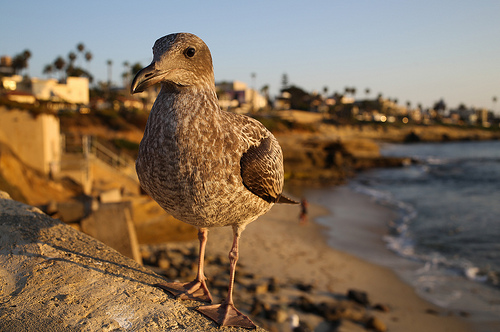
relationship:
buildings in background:
[270, 85, 321, 115] [223, 22, 495, 120]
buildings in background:
[449, 105, 488, 125] [223, 22, 495, 120]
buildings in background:
[353, 100, 415, 120] [223, 22, 495, 120]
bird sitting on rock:
[128, 30, 302, 329] [2, 198, 208, 330]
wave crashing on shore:
[391, 225, 470, 292] [360, 217, 484, 328]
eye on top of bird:
[183, 46, 200, 58] [128, 30, 302, 329]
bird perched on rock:
[128, 30, 302, 329] [1, 197, 270, 329]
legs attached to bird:
[153, 226, 262, 330] [128, 30, 302, 329]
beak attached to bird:
[126, 63, 168, 94] [128, 30, 302, 329]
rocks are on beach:
[259, 276, 309, 316] [242, 251, 471, 331]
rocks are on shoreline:
[328, 144, 405, 176] [331, 164, 445, 295]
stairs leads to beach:
[81, 133, 132, 178] [313, 190, 435, 330]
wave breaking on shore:
[391, 225, 470, 292] [313, 173, 455, 311]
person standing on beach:
[299, 197, 311, 219] [158, 170, 433, 327]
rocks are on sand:
[259, 276, 379, 326] [89, 161, 430, 330]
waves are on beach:
[353, 172, 497, 292] [293, 171, 463, 303]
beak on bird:
[126, 63, 168, 94] [107, 24, 332, 268]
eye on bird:
[178, 42, 200, 59] [128, 30, 302, 329]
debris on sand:
[260, 274, 397, 326] [276, 252, 384, 327]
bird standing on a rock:
[128, 31, 302, 328] [2, 201, 153, 330]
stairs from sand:
[81, 133, 138, 193] [205, 183, 498, 328]